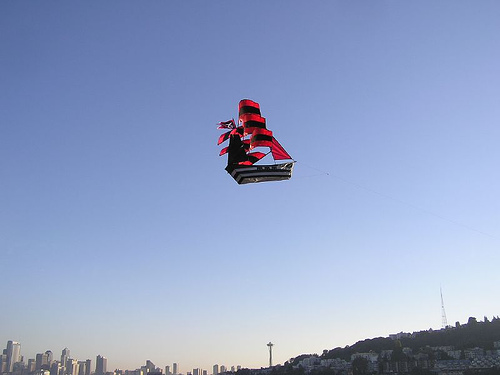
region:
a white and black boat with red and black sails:
[213, 99, 305, 190]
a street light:
[264, 340, 278, 366]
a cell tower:
[436, 281, 451, 329]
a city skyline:
[3, 335, 238, 373]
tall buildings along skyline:
[4, 336, 112, 372]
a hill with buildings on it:
[246, 320, 496, 373]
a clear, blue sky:
[3, 6, 217, 353]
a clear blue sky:
[300, 9, 499, 316]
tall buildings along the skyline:
[129, 357, 250, 372]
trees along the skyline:
[477, 315, 499, 327]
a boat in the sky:
[209, 96, 298, 188]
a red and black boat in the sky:
[215, 97, 307, 184]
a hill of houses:
[337, 321, 496, 373]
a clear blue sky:
[32, 11, 196, 218]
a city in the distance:
[0, 339, 114, 374]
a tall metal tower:
[265, 342, 272, 367]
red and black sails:
[237, 96, 272, 153]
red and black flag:
[219, 120, 236, 134]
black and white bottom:
[234, 165, 289, 182]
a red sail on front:
[274, 142, 291, 161]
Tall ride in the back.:
[258, 330, 283, 367]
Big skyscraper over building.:
[427, 275, 459, 333]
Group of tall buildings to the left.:
[1, 332, 113, 367]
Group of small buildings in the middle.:
[137, 353, 261, 373]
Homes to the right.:
[333, 338, 454, 373]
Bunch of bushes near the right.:
[403, 321, 495, 347]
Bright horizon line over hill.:
[316, 311, 443, 341]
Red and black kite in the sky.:
[221, 98, 307, 189]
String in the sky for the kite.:
[293, 131, 481, 268]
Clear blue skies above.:
[31, 90, 162, 278]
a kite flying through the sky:
[198, 97, 315, 194]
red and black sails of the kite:
[228, 85, 277, 157]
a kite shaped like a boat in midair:
[209, 90, 297, 191]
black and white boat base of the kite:
[228, 158, 305, 199]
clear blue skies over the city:
[53, 83, 179, 260]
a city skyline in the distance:
[0, 340, 175, 374]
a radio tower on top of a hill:
[432, 288, 455, 330]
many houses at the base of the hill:
[304, 343, 499, 373]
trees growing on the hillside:
[356, 334, 487, 348]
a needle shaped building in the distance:
[262, 339, 279, 366]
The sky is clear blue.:
[3, 7, 481, 308]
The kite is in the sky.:
[187, 84, 297, 206]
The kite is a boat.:
[200, 92, 307, 199]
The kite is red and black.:
[214, 88, 299, 187]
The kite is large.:
[190, 78, 300, 188]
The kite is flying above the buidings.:
[158, 53, 478, 373]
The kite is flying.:
[200, 93, 296, 184]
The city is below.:
[13, 335, 488, 374]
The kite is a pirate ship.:
[203, 95, 305, 185]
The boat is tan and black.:
[208, 90, 297, 188]